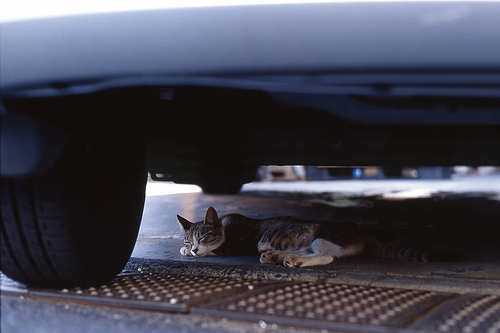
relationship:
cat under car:
[177, 204, 434, 269] [2, 0, 500, 292]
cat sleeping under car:
[177, 204, 434, 269] [2, 0, 500, 292]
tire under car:
[1, 95, 147, 289] [2, 0, 500, 292]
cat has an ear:
[177, 204, 434, 269] [204, 204, 220, 225]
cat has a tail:
[177, 204, 434, 269] [366, 233, 442, 264]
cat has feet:
[177, 204, 434, 269] [259, 247, 336, 268]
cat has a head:
[177, 204, 434, 269] [175, 204, 227, 255]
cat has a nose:
[177, 204, 434, 269] [192, 246, 198, 255]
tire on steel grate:
[1, 95, 147, 289] [2, 266, 499, 332]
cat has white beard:
[177, 204, 434, 269] [192, 243, 221, 257]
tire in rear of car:
[1, 95, 147, 289] [2, 0, 500, 292]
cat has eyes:
[177, 204, 434, 269] [181, 233, 208, 247]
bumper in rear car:
[1, 1, 499, 97] [2, 0, 500, 292]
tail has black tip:
[366, 233, 442, 264] [431, 253, 440, 263]